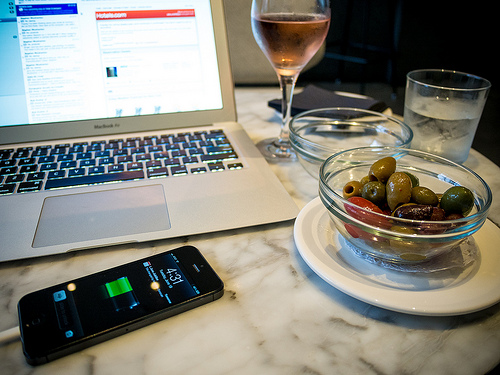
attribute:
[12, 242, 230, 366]
iphone — black, charging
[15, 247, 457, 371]
table — granite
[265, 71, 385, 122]
napkins — black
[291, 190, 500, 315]
plate — white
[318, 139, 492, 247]
bowl — clear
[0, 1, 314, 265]
laptop — white, computer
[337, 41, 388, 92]
chair arms — black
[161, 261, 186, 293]
time — 4:31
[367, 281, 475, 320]
white plate — circular shaped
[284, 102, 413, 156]
dish — empty